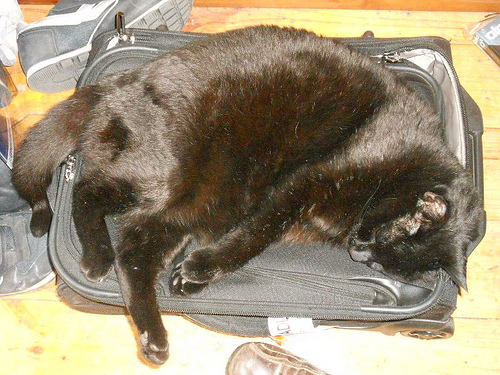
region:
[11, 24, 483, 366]
A black cat lying on a suitcase.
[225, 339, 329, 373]
A brown shoe by a suitcase.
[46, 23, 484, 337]
A black suitcase with a cat on it.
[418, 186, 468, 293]
Black ears of a cat.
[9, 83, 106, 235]
A black tail on a black cat.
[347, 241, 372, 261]
Black nose on a black cat.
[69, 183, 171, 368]
A black cats back long feet.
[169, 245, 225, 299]
Two black front paws of a cat.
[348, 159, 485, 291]
Black head of a black cat.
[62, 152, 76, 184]
Zipper between a cat's tail and butt.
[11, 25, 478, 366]
a black cat sleeping on the suitcase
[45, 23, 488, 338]
a small, black suitcase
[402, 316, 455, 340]
black wheel of the suitcase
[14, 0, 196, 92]
black tennis shoe above suitcase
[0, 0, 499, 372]
wooden floor under cat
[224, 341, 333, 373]
part of a brown shoe in front of the suitcase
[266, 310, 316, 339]
white tag on the suitcase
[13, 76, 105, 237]
black tail of the cat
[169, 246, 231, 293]
clasped front paws of the cat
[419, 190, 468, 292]
ears on the cat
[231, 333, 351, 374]
brown color shoe near the bag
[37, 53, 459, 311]
black color cat is sleeping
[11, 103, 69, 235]
tail of the cat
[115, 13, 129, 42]
zipper of the bag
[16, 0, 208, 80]
grey color shoe in the bag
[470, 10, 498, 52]
book in the floor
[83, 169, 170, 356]
leg of the black color cat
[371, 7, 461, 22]
brown color tiles in the floor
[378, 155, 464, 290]
head of the cat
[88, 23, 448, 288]
cat is sleeping in the bag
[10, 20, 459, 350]
Black cat sleeping on a platter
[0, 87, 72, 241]
Black tail on cat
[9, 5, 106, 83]
Grey tennis shoe on side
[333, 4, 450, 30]
Wooden table under cat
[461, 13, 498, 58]
corner of a book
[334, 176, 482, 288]
Cat head laying on the suitcase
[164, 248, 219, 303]
paw of a cat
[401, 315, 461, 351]
Wheel of suitcase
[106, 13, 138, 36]
zipper of suit case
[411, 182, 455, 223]
Ear of a cat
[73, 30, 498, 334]
a cat is sleeping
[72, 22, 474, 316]
a black cat is sleeping the bag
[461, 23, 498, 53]
book kept near the bag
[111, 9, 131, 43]
zipper in the bag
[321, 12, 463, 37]
brown color floor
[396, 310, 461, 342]
black color wheel of the bag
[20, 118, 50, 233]
tail of the cat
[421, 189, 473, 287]
ears of the cat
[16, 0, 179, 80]
shoe near the bag